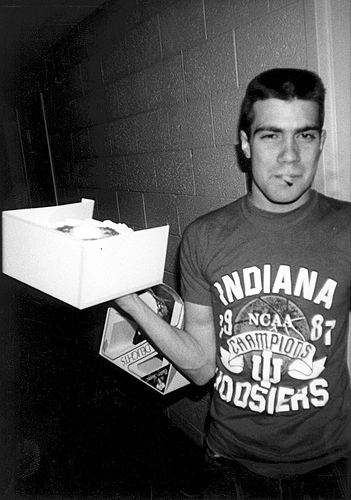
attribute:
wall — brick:
[34, 4, 349, 171]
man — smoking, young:
[109, 66, 349, 497]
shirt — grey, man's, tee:
[168, 187, 348, 481]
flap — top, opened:
[54, 196, 181, 294]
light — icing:
[71, 212, 115, 256]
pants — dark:
[208, 457, 348, 497]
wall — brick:
[13, 0, 338, 225]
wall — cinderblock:
[35, 2, 349, 259]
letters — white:
[214, 264, 337, 309]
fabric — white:
[206, 259, 330, 422]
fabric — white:
[212, 257, 326, 428]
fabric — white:
[196, 255, 338, 421]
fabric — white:
[207, 250, 337, 424]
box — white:
[0, 176, 209, 329]